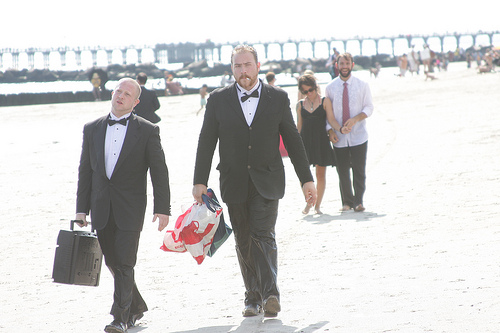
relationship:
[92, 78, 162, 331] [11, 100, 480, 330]
man walking on beach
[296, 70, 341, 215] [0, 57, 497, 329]
person walking on beach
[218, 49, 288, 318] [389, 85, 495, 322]
man walking on beach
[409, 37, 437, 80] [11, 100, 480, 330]
person walking on beach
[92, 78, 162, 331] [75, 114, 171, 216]
man wearing black jacket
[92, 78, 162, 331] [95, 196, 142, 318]
man wearing pants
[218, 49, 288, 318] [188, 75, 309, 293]
man wearing coat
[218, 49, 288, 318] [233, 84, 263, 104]
man wearing tie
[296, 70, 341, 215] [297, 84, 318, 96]
person wearing sun shades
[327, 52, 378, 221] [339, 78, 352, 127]
man wearing tie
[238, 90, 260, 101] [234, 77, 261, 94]
bowtie on neck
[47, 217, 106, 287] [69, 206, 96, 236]
stereo in hand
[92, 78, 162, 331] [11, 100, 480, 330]
man on beach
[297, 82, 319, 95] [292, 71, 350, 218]
sunglasses worn by girl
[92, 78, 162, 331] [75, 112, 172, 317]
man in suit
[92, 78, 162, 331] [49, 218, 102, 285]
man carrying case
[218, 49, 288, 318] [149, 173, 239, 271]
man with bags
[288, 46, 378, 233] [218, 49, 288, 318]
couple behind man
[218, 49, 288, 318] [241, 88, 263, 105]
man has bow tie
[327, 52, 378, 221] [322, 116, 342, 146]
man holding hands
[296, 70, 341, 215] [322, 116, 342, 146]
person holding hands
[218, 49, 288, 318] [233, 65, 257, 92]
man smoking cigarette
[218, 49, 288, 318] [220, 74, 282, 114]
man wearing bowtie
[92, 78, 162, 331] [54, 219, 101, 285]
man carrying briefcase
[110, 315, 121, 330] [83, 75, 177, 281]
foot of man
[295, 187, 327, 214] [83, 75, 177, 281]
foot of man